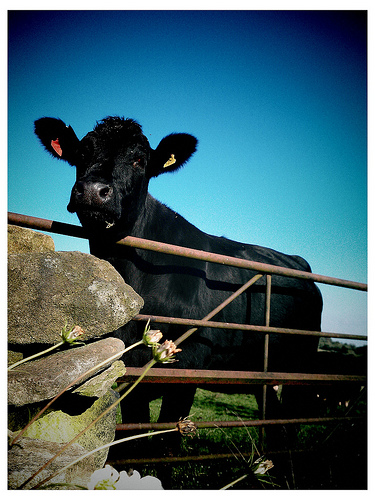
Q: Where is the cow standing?
A: Behind the gate.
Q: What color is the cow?
A: Black.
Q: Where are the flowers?
A: On the rocks.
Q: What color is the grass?
A: Green.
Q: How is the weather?
A: Sunny.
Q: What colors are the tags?
A: Red,yellow.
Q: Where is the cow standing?
A: Next to gate.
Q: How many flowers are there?
A: 5.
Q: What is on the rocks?
A: Moss.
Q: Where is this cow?
A: In the pasture.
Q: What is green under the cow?
A: Grass.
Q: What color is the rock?
A: Gray, white, olive green.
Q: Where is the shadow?
A: On the rock.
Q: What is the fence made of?
A: Metal.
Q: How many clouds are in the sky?
A: None.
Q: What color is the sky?
A: Blue.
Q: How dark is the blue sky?
A: Light shading to dark.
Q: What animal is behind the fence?
A: Steer.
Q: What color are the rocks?
A: Grey.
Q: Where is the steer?
A: In a field.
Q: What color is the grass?
A: Green.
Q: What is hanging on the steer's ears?
A: Ear tags.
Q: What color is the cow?
A: Black.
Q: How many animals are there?
A: One.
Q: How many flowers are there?
A: Five.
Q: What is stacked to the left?
A: Rocks.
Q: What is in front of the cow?
A: A fence.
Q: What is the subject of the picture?
A: The cow.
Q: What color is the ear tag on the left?
A: Red.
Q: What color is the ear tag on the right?
A: Yellow.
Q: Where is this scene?
A: A farm.